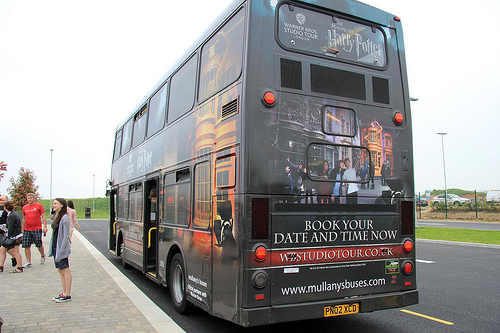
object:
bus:
[106, 1, 419, 328]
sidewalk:
[1, 224, 185, 331]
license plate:
[324, 303, 360, 317]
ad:
[275, 101, 397, 296]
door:
[143, 176, 162, 278]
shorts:
[22, 229, 43, 248]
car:
[431, 193, 472, 206]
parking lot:
[416, 191, 499, 215]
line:
[400, 308, 455, 325]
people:
[47, 197, 72, 302]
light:
[263, 92, 275, 104]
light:
[395, 112, 403, 122]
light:
[255, 246, 266, 259]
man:
[23, 192, 48, 268]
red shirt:
[22, 203, 45, 232]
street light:
[437, 132, 448, 219]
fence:
[418, 191, 500, 221]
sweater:
[48, 214, 72, 262]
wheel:
[169, 253, 191, 313]